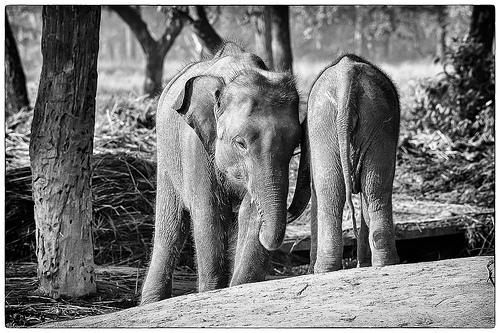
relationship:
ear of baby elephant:
[170, 58, 221, 141] [139, 39, 300, 304]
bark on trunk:
[42, 50, 85, 245] [22, 6, 107, 303]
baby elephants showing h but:
[300, 51, 401, 273] [304, 61, 402, 175]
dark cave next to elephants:
[395, 227, 460, 263] [288, 61, 410, 278]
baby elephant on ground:
[139, 39, 300, 304] [292, 258, 481, 328]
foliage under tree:
[416, 54, 498, 218] [462, 6, 482, 62]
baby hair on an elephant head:
[221, 55, 306, 107] [212, 63, 302, 192]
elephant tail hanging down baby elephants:
[335, 86, 361, 253] [300, 51, 401, 273]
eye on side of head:
[229, 127, 249, 154] [182, 69, 297, 233]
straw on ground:
[15, 118, 167, 246] [36, 198, 375, 287]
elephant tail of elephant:
[335, 86, 361, 253] [300, 58, 424, 261]